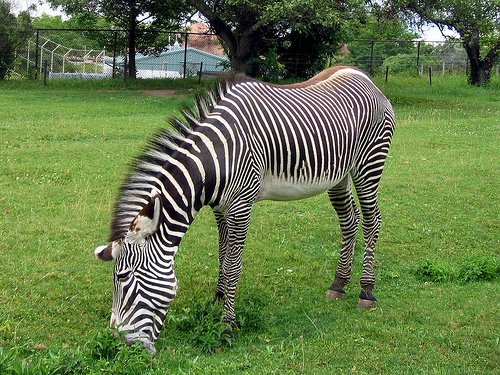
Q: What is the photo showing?
A: It is showing a field.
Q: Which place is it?
A: It is a field.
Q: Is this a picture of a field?
A: Yes, it is showing a field.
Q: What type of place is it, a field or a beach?
A: It is a field.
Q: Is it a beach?
A: No, it is a field.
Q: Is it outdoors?
A: Yes, it is outdoors.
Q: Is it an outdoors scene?
A: Yes, it is outdoors.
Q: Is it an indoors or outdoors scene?
A: It is outdoors.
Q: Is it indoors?
A: No, it is outdoors.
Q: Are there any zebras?
A: Yes, there is a zebra.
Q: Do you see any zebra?
A: Yes, there is a zebra.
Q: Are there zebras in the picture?
A: Yes, there is a zebra.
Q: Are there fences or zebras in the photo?
A: Yes, there is a zebra.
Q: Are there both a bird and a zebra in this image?
A: No, there is a zebra but no birds.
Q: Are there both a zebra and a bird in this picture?
A: No, there is a zebra but no birds.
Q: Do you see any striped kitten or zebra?
A: Yes, there is a striped zebra.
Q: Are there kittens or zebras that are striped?
A: Yes, the zebra is striped.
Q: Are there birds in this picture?
A: No, there are no birds.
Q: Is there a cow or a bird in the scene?
A: No, there are no birds or cows.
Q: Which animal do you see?
A: The animal is a zebra.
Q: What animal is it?
A: The animal is a zebra.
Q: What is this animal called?
A: This is a zebra.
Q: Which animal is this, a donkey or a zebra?
A: This is a zebra.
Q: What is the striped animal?
A: The animal is a zebra.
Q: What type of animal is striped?
A: The animal is a zebra.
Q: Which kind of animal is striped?
A: The animal is a zebra.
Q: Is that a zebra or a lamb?
A: That is a zebra.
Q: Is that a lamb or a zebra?
A: That is a zebra.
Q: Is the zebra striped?
A: Yes, the zebra is striped.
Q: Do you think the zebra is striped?
A: Yes, the zebra is striped.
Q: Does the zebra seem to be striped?
A: Yes, the zebra is striped.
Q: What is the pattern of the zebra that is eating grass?
A: The zebra is striped.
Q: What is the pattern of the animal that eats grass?
A: The zebra is striped.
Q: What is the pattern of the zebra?
A: The zebra is striped.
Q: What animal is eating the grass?
A: The animal is a zebra.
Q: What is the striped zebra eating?
A: The zebra is eating grass.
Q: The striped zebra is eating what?
A: The zebra is eating grass.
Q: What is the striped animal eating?
A: The zebra is eating grass.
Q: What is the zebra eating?
A: The zebra is eating grass.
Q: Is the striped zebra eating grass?
A: Yes, the zebra is eating grass.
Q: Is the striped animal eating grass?
A: Yes, the zebra is eating grass.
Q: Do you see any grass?
A: Yes, there is grass.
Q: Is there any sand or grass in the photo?
A: Yes, there is grass.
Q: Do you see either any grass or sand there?
A: Yes, there is grass.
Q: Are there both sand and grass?
A: No, there is grass but no sand.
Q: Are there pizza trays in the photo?
A: No, there are no pizza trays.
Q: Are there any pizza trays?
A: No, there are no pizza trays.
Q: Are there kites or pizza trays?
A: No, there are no pizza trays or kites.